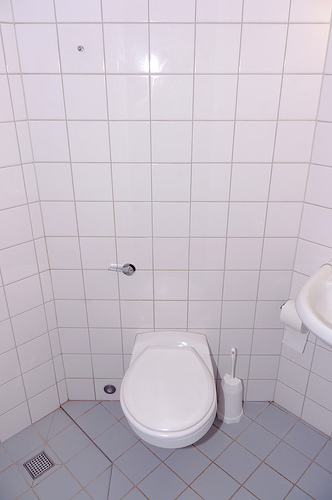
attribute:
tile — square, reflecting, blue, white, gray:
[150, 25, 193, 77]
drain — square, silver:
[24, 450, 56, 478]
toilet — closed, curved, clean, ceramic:
[120, 331, 217, 450]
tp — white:
[278, 300, 310, 359]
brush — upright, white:
[230, 350, 240, 378]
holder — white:
[220, 378, 245, 426]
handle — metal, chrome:
[109, 263, 137, 277]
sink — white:
[298, 264, 331, 347]